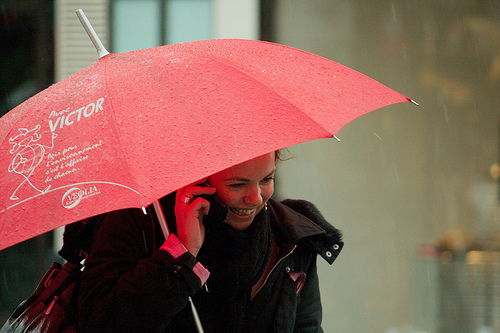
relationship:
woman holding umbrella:
[84, 148, 328, 331] [3, 7, 418, 330]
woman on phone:
[84, 148, 328, 331] [200, 179, 229, 224]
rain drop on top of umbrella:
[200, 84, 210, 91] [3, 7, 418, 330]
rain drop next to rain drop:
[184, 62, 191, 69] [196, 63, 203, 69]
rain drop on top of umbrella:
[245, 54, 252, 62] [3, 7, 418, 330]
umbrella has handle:
[3, 7, 418, 330] [150, 192, 212, 332]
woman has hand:
[84, 148, 328, 331] [171, 176, 220, 258]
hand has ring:
[171, 176, 220, 258] [180, 195, 191, 206]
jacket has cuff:
[81, 194, 334, 332] [162, 234, 214, 287]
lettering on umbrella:
[43, 97, 124, 185] [3, 7, 418, 330]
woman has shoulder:
[84, 148, 328, 331] [76, 202, 162, 268]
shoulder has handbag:
[76, 202, 162, 268] [1, 214, 127, 330]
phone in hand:
[200, 179, 229, 224] [171, 176, 220, 258]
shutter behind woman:
[51, 4, 110, 79] [84, 148, 328, 331]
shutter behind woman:
[210, 3, 267, 44] [84, 148, 328, 331]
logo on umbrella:
[11, 124, 56, 206] [3, 7, 418, 330]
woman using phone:
[84, 148, 328, 331] [200, 179, 229, 224]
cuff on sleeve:
[162, 234, 214, 287] [78, 212, 199, 330]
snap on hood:
[325, 249, 331, 258] [272, 193, 351, 272]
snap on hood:
[331, 242, 346, 253] [272, 193, 351, 272]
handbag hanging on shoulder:
[1, 214, 127, 330] [76, 202, 162, 268]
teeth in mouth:
[230, 204, 256, 214] [228, 203, 263, 218]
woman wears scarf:
[84, 148, 328, 331] [207, 210, 275, 332]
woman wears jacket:
[84, 148, 328, 331] [81, 194, 334, 332]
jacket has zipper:
[81, 194, 334, 332] [246, 238, 304, 295]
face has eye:
[209, 152, 276, 230] [229, 181, 246, 191]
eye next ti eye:
[262, 174, 275, 185] [229, 181, 246, 191]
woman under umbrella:
[84, 148, 328, 331] [3, 7, 418, 330]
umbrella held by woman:
[3, 7, 418, 330] [84, 148, 328, 331]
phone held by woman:
[200, 179, 229, 224] [84, 148, 328, 331]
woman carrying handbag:
[84, 148, 328, 331] [1, 214, 127, 330]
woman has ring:
[84, 148, 328, 331] [180, 195, 191, 206]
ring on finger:
[180, 195, 191, 206] [180, 184, 215, 203]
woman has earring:
[84, 148, 328, 331] [262, 199, 269, 212]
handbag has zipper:
[1, 214, 127, 330] [45, 293, 60, 317]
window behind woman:
[110, 3, 217, 55] [84, 148, 328, 331]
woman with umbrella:
[84, 148, 328, 331] [3, 7, 418, 330]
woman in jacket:
[84, 148, 328, 331] [81, 194, 334, 332]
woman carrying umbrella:
[84, 148, 328, 331] [3, 7, 418, 330]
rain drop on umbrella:
[184, 62, 191, 69] [3, 7, 418, 330]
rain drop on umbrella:
[196, 63, 203, 69] [3, 7, 418, 330]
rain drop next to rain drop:
[200, 84, 210, 91] [245, 54, 252, 62]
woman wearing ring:
[84, 148, 328, 331] [180, 195, 191, 206]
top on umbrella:
[75, 7, 110, 62] [3, 7, 418, 330]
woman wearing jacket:
[84, 148, 328, 331] [81, 194, 334, 332]